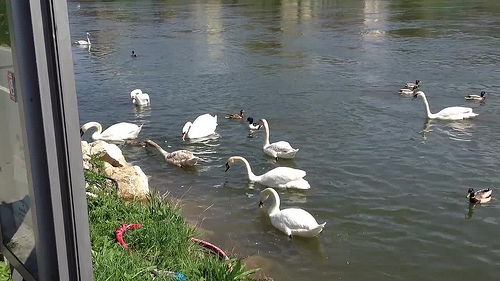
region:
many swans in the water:
[67, 45, 474, 261]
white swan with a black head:
[218, 136, 316, 208]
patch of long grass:
[56, 153, 228, 274]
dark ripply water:
[183, 36, 459, 235]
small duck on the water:
[462, 174, 493, 206]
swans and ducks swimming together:
[96, 29, 494, 251]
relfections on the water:
[142, 4, 434, 91]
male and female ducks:
[223, 105, 265, 140]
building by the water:
[13, 5, 84, 278]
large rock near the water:
[91, 134, 165, 234]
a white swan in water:
[254, 187, 329, 240]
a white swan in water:
[216, 152, 314, 195]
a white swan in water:
[241, 114, 301, 163]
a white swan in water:
[410, 89, 474, 126]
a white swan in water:
[177, 109, 225, 144]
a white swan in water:
[78, 114, 152, 147]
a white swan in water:
[128, 85, 153, 111]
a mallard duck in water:
[463, 182, 498, 210]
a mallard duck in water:
[241, 112, 262, 130]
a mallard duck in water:
[126, 47, 138, 59]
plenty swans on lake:
[180, 98, 320, 263]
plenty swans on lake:
[184, 25, 362, 243]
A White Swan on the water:
[256, 187, 344, 239]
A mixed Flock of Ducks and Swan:
[72, 26, 498, 231]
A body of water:
[198, 7, 453, 68]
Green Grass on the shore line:
[91, 186, 198, 279]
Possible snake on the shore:
[115, 217, 230, 268]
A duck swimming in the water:
[459, 179, 499, 211]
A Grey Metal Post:
[0, 0, 110, 277]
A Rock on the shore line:
[68, 135, 158, 199]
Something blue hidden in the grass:
[171, 269, 196, 279]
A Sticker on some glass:
[3, 69, 20, 104]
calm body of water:
[68, 1, 498, 279]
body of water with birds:
[68, 1, 499, 279]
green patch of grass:
[82, 150, 261, 279]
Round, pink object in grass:
[115, 217, 234, 279]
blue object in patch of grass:
[171, 267, 191, 279]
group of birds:
[74, 29, 495, 237]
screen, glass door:
[0, 0, 92, 279]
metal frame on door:
[8, 0, 100, 280]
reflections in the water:
[153, 2, 410, 64]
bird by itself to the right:
[466, 182, 494, 205]